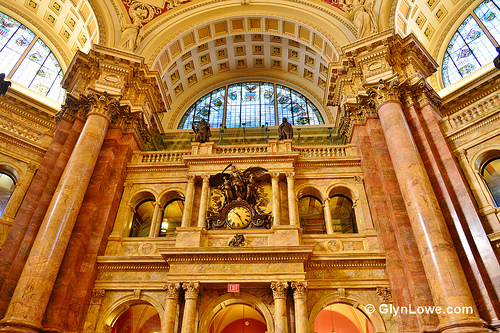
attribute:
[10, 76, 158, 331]
pillar — tall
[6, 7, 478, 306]
building — old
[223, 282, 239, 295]
sign — red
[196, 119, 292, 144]
statue — high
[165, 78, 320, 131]
window — stained, colorfull, arched, up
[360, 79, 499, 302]
column — marble, big, brown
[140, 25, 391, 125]
ceiling — arched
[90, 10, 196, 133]
molding — yellow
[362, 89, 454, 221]
marble — red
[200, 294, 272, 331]
doorway — arched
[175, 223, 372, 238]
rail — carved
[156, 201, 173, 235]
light — hanging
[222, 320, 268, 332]
entrance — colorful